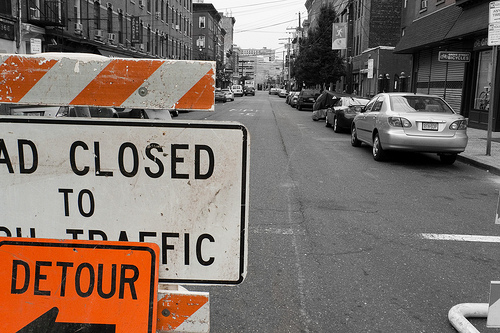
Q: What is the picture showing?
A: It is showing a city.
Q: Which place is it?
A: It is a city.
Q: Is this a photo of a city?
A: Yes, it is showing a city.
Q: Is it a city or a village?
A: It is a city.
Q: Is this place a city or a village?
A: It is a city.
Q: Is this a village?
A: No, it is a city.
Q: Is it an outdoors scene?
A: Yes, it is outdoors.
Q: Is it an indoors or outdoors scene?
A: It is outdoors.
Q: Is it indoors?
A: No, it is outdoors.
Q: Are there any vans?
A: No, there are no vans.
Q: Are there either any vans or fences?
A: No, there are no vans or fences.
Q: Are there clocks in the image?
A: No, there are no clocks.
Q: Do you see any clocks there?
A: No, there are no clocks.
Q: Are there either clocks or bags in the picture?
A: No, there are no clocks or bags.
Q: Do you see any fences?
A: No, there are no fences.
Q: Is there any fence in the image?
A: No, there are no fences.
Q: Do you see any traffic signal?
A: No, there are no traffic lights.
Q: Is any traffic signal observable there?
A: No, there are no traffic lights.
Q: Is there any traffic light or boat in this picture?
A: No, there are no traffic lights or boats.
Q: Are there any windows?
A: Yes, there is a window.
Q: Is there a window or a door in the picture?
A: Yes, there is a window.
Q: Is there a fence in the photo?
A: No, there are no fences.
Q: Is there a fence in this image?
A: No, there are no fences.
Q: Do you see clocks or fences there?
A: No, there are no fences or clocks.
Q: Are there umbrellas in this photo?
A: No, there are no umbrellas.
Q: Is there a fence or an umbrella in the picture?
A: No, there are no umbrellas or fences.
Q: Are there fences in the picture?
A: No, there are no fences.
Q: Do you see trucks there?
A: No, there are no trucks.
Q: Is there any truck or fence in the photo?
A: No, there are no trucks or fences.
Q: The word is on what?
A: The word is on the sign.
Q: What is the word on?
A: The word is on the sign.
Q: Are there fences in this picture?
A: No, there are no fences.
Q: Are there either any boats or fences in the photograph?
A: No, there are no fences or boats.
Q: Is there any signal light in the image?
A: No, there are no traffic lights.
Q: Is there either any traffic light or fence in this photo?
A: No, there are no traffic lights or fences.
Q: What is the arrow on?
A: The arrow is on the sign.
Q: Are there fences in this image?
A: No, there are no fences.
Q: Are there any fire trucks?
A: No, there are no fire trucks.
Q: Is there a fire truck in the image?
A: No, there are no fire trucks.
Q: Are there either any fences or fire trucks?
A: No, there are no fire trucks or fences.